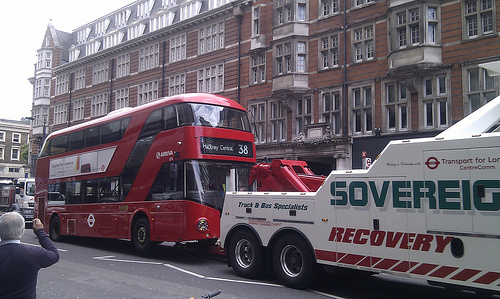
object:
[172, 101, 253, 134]
window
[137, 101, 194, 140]
window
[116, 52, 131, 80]
window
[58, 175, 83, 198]
side window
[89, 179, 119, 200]
side window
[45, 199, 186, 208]
level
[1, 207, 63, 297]
man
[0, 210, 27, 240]
hair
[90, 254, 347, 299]
line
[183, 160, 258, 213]
windshield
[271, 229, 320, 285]
wheels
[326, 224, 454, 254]
red lettering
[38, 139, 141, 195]
sign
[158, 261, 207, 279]
lines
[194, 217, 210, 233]
headlight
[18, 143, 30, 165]
tree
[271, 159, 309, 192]
mechanism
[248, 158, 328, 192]
truck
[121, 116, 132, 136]
window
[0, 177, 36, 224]
truck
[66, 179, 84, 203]
windows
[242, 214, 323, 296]
tire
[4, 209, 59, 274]
man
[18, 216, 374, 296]
road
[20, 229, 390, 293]
road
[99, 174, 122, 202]
windows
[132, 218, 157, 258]
wheel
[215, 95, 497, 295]
truck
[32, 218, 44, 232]
hand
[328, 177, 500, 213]
lettering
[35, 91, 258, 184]
upper level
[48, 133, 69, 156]
window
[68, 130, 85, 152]
window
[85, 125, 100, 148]
window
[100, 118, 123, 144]
window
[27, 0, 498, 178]
building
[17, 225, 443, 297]
street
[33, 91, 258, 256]
bus